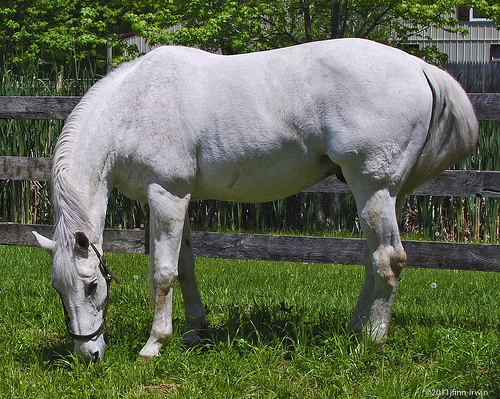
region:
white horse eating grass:
[23, 32, 490, 379]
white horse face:
[29, 219, 126, 371]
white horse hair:
[47, 101, 107, 247]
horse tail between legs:
[361, 42, 496, 214]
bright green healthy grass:
[238, 259, 336, 369]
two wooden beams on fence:
[438, 169, 498, 282]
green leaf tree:
[4, 7, 89, 86]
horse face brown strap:
[34, 230, 132, 373]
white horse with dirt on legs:
[343, 137, 419, 362]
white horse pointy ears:
[22, 216, 97, 259]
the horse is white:
[15, 97, 372, 352]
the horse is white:
[56, 67, 256, 396]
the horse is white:
[39, 58, 270, 237]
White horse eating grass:
[20, 40, 480, 358]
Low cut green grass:
[1, 272, 480, 391]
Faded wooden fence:
[7, 82, 493, 287]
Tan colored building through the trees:
[394, 5, 499, 74]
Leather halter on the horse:
[23, 227, 123, 377]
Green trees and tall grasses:
[3, 3, 59, 277]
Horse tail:
[385, 42, 482, 228]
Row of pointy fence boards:
[427, 52, 499, 91]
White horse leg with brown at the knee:
[132, 232, 187, 364]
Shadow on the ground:
[117, 269, 492, 364]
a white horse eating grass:
[33, 33, 478, 370]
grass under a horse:
[2, 240, 498, 393]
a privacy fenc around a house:
[448, 58, 499, 91]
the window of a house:
[462, 4, 496, 26]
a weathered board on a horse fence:
[198, 226, 381, 263]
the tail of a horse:
[397, 63, 482, 200]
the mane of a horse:
[42, 54, 134, 247]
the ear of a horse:
[72, 228, 93, 253]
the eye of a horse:
[87, 278, 103, 296]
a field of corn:
[1, 73, 497, 230]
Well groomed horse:
[9, 34, 483, 384]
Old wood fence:
[7, 87, 474, 282]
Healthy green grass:
[225, 269, 348, 392]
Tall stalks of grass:
[436, 124, 498, 229]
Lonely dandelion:
[424, 277, 444, 322]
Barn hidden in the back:
[340, 0, 498, 99]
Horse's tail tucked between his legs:
[398, 46, 483, 232]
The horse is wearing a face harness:
[32, 222, 118, 359]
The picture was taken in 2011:
[422, 377, 450, 395]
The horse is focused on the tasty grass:
[25, 221, 152, 394]